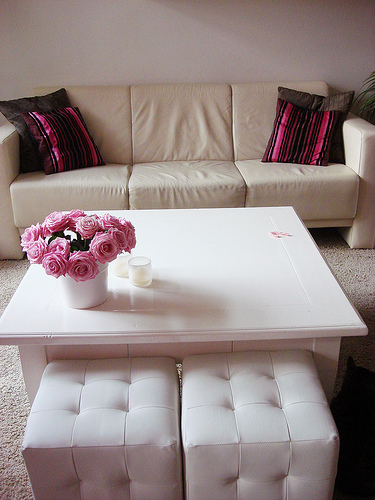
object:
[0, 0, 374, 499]
living room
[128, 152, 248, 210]
cushion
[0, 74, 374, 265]
couch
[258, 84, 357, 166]
pillow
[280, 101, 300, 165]
stripes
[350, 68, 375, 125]
plant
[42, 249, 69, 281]
roses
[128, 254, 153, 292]
candle holder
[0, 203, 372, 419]
table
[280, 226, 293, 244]
ribbon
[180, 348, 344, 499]
ottoman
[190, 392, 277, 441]
cloth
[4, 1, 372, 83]
wall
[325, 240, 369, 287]
carpet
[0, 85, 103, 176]
pillow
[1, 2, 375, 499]
photo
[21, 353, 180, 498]
ottoman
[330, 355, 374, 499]
cat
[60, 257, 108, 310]
container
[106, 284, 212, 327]
shadow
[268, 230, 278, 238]
petals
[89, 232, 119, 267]
rose